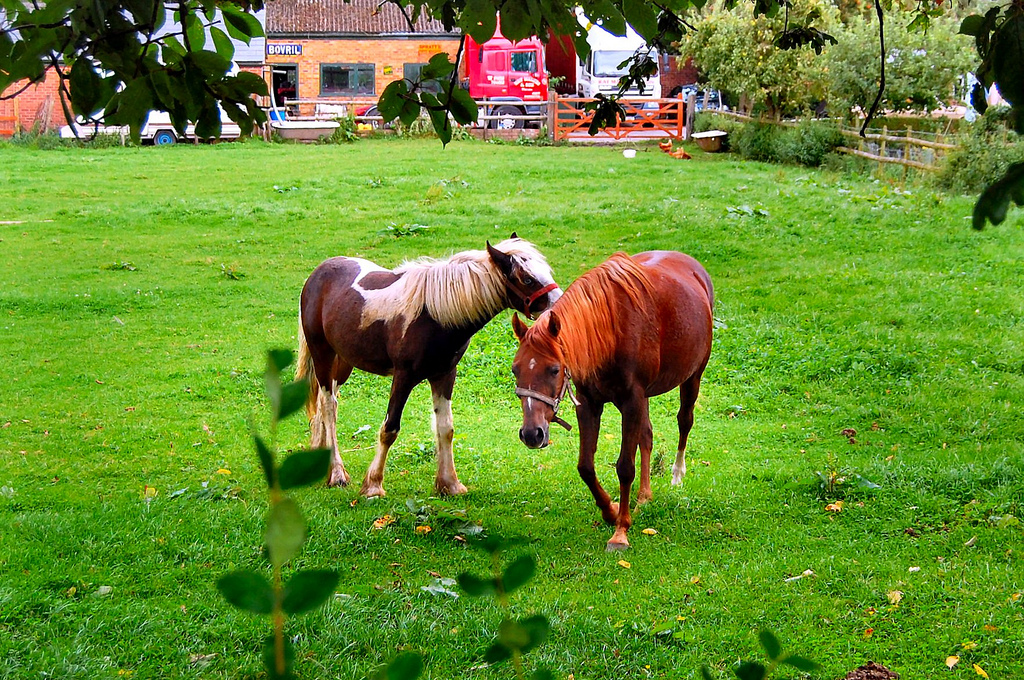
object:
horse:
[510, 250, 714, 552]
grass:
[5, 135, 1021, 679]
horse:
[294, 231, 564, 497]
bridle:
[514, 367, 582, 431]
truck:
[359, 39, 551, 134]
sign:
[266, 43, 302, 55]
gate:
[553, 90, 692, 145]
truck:
[575, 43, 662, 128]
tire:
[153, 130, 177, 146]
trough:
[269, 122, 338, 142]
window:
[318, 62, 376, 97]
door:
[271, 62, 299, 120]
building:
[263, 0, 477, 122]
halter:
[521, 284, 556, 320]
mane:
[388, 237, 550, 341]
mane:
[520, 251, 655, 390]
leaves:
[377, 52, 479, 149]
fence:
[279, 98, 561, 138]